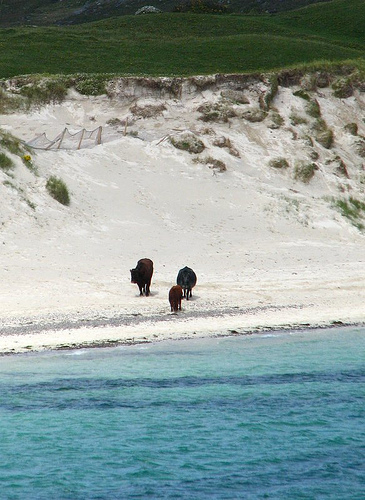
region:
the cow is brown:
[125, 247, 179, 310]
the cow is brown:
[164, 276, 186, 315]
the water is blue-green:
[23, 374, 68, 427]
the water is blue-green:
[135, 365, 217, 446]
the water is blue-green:
[243, 334, 306, 446]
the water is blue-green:
[132, 414, 264, 483]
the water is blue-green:
[151, 407, 190, 417]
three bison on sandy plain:
[125, 246, 201, 313]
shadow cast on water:
[55, 372, 341, 404]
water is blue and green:
[60, 399, 321, 477]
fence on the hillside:
[34, 124, 148, 150]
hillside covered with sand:
[62, 159, 250, 244]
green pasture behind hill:
[98, 57, 270, 76]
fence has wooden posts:
[65, 114, 142, 152]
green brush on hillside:
[283, 90, 348, 184]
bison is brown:
[123, 256, 163, 299]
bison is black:
[177, 269, 197, 300]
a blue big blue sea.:
[5, 385, 362, 459]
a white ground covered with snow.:
[110, 193, 201, 225]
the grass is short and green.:
[133, 26, 249, 66]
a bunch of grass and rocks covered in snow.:
[160, 75, 359, 170]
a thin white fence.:
[17, 118, 111, 153]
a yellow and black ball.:
[11, 146, 37, 171]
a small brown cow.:
[159, 280, 187, 315]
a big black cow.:
[170, 251, 194, 295]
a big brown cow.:
[120, 243, 159, 310]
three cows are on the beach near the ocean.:
[105, 238, 220, 328]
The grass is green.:
[0, 4, 364, 82]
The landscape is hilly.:
[3, 1, 364, 83]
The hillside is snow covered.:
[2, 74, 363, 343]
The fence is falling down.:
[2, 100, 203, 181]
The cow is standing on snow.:
[58, 232, 163, 313]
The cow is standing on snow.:
[174, 253, 274, 311]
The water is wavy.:
[1, 321, 364, 498]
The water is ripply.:
[1, 318, 363, 498]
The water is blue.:
[1, 319, 363, 497]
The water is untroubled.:
[1, 317, 363, 498]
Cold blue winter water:
[124, 412, 211, 444]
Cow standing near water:
[130, 256, 155, 295]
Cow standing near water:
[168, 285, 186, 314]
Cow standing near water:
[175, 265, 196, 300]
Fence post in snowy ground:
[74, 126, 82, 147]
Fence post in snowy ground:
[94, 125, 104, 150]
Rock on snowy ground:
[167, 129, 206, 153]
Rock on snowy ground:
[267, 157, 289, 170]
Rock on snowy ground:
[129, 93, 170, 116]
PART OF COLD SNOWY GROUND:
[231, 230, 285, 265]